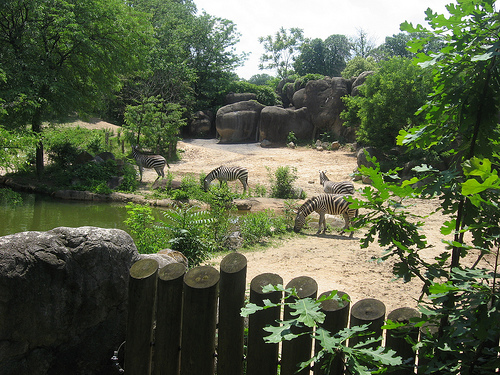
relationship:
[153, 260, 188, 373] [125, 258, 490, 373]
post on fence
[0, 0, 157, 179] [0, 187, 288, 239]
tree side pond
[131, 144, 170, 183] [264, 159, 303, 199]
zebra behind bush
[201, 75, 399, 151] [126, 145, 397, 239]
rock wall behind animals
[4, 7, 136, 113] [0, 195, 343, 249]
tree beside water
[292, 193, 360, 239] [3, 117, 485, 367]
zebra on dirt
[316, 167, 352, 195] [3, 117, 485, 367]
zebra on dirt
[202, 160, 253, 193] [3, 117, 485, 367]
zebra on dirt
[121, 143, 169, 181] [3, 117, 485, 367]
zebra on dirt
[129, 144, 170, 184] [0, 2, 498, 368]
giraffe standing in zoo